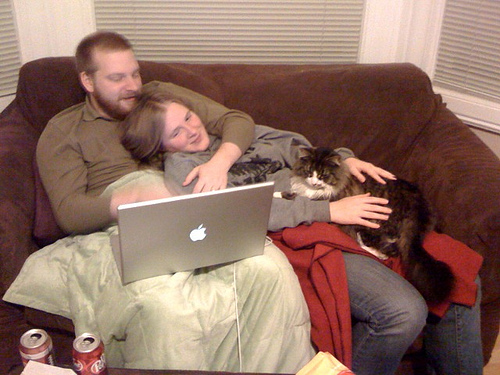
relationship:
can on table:
[72, 331, 106, 372] [10, 350, 287, 372]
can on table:
[19, 323, 53, 365] [10, 350, 287, 372]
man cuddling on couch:
[34, 30, 257, 233] [172, 50, 499, 266]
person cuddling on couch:
[114, 98, 304, 221] [172, 50, 499, 266]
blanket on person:
[264, 219, 485, 372] [118, 94, 488, 374]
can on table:
[17, 325, 56, 365] [0, 363, 311, 372]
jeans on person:
[302, 195, 499, 353] [118, 94, 488, 374]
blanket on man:
[0, 166, 318, 374] [31, 27, 256, 373]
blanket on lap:
[265, 221, 483, 367] [102, 215, 284, 294]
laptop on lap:
[102, 176, 279, 286] [78, 207, 300, 373]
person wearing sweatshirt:
[118, 94, 488, 374] [163, 117, 335, 225]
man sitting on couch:
[34, 30, 257, 233] [12, 51, 499, 291]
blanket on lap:
[109, 285, 308, 372] [78, 218, 297, 302]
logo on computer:
[187, 218, 212, 248] [142, 172, 268, 277]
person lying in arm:
[118, 94, 488, 374] [171, 77, 255, 186]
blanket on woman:
[264, 219, 485, 372] [137, 85, 474, 358]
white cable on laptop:
[229, 263, 259, 373] [106, 178, 274, 287]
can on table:
[70, 330, 108, 374] [107, 359, 299, 374]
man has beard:
[71, 30, 144, 116] [87, 80, 144, 121]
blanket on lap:
[265, 221, 483, 367] [266, 223, 478, 278]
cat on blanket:
[277, 142, 454, 310] [432, 228, 477, 305]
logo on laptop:
[187, 221, 209, 244] [102, 176, 279, 286]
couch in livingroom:
[2, 55, 496, 373] [0, 0, 499, 375]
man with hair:
[34, 30, 257, 233] [62, 23, 144, 109]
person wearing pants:
[118, 94, 488, 374] [324, 228, 475, 373]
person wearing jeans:
[118, 94, 488, 374] [340, 247, 485, 375]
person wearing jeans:
[118, 94, 488, 374] [331, 235, 486, 372]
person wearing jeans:
[118, 94, 488, 374] [343, 251, 481, 373]